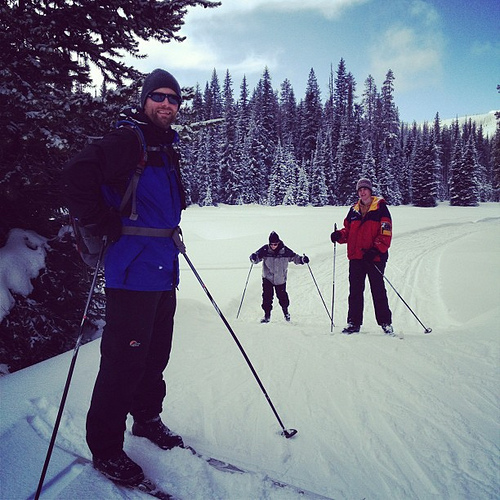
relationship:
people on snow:
[63, 68, 186, 486] [0, 200, 498, 497]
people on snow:
[249, 230, 309, 324] [0, 200, 498, 497]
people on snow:
[331, 178, 393, 336] [0, 200, 498, 497]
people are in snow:
[331, 178, 393, 336] [0, 200, 498, 497]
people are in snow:
[249, 230, 309, 324] [0, 200, 498, 497]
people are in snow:
[63, 68, 186, 486] [0, 200, 498, 497]